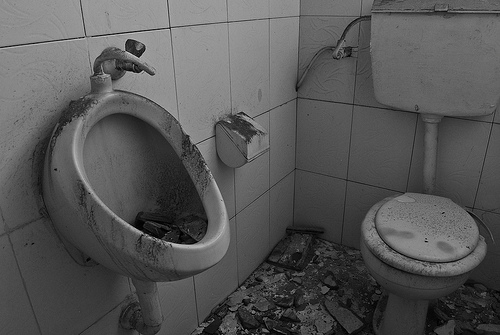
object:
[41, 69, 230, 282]
urinal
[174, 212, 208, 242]
rocks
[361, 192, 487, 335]
toilet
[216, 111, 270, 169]
holder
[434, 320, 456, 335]
debris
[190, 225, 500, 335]
floor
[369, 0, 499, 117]
tank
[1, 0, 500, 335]
wall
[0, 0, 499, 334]
tile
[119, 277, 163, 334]
pipe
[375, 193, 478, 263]
cover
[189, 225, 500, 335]
tile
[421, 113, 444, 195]
pipe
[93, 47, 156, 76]
hose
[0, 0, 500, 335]
bathroom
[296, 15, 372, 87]
hose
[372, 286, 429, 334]
base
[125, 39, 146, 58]
knob